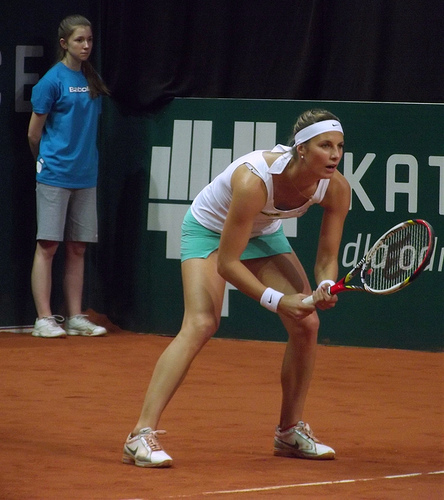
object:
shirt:
[29, 59, 104, 190]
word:
[68, 86, 91, 93]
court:
[0, 319, 444, 500]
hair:
[55, 13, 93, 48]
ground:
[4, 320, 438, 495]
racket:
[343, 217, 434, 296]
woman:
[115, 109, 354, 471]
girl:
[26, 12, 109, 341]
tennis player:
[115, 102, 352, 473]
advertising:
[128, 98, 444, 357]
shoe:
[119, 423, 175, 471]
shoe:
[272, 421, 337, 461]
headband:
[295, 118, 346, 147]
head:
[287, 105, 349, 179]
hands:
[278, 292, 316, 323]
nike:
[267, 293, 273, 304]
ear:
[296, 144, 306, 160]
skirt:
[179, 207, 298, 264]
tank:
[188, 146, 331, 243]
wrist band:
[259, 287, 283, 313]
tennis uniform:
[178, 141, 329, 265]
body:
[168, 146, 342, 261]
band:
[259, 286, 284, 313]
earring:
[300, 154, 304, 159]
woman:
[25, 10, 109, 340]